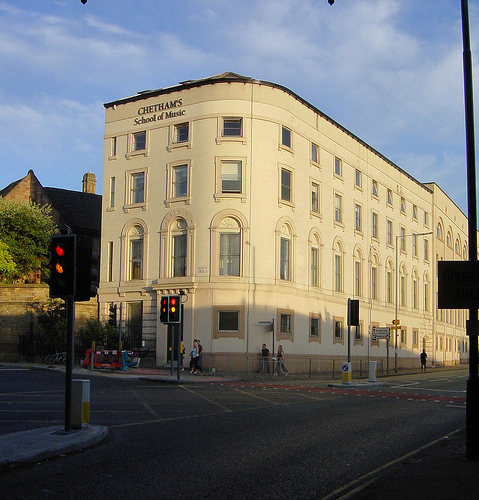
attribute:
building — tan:
[95, 72, 477, 376]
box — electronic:
[342, 363, 350, 382]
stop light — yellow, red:
[156, 289, 184, 382]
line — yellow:
[312, 415, 460, 498]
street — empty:
[3, 364, 473, 495]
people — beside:
[179, 338, 202, 374]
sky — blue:
[0, 2, 474, 192]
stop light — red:
[45, 232, 87, 310]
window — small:
[218, 310, 239, 331]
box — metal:
[68, 376, 84, 431]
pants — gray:
[274, 355, 287, 371]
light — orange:
[52, 261, 64, 274]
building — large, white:
[58, 50, 465, 384]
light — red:
[151, 287, 181, 321]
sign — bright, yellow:
[385, 313, 406, 345]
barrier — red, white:
[80, 345, 130, 370]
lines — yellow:
[102, 359, 377, 441]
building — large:
[57, 81, 388, 351]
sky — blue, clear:
[3, 2, 468, 218]